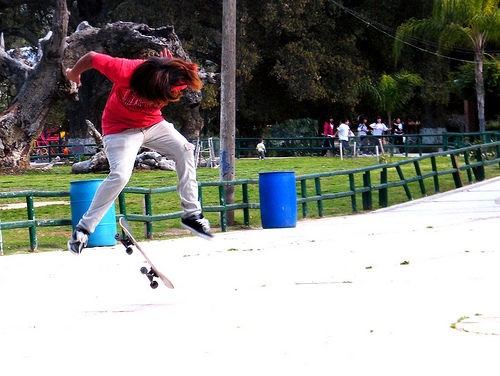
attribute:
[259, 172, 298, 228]
barrel — small, darker blue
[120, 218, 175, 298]
skateboard — black, wooden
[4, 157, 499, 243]
fence — green, wooden, small, metal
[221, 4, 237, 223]
pole — brown, wooden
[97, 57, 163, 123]
t-shirt — red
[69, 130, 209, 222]
pants — gray, khaki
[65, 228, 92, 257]
shoes — black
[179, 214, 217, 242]
shoes — black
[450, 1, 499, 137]
tree — young, tall, green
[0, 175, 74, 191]
grass — green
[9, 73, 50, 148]
tree trunk — brown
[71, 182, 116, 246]
trash can — jewel toned blue, lighter blue, blue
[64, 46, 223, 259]
skateboarder — young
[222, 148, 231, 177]
paint spot — blue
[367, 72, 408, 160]
weeping tree — young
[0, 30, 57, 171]
dead tree — large, gnarled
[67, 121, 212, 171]
branch — huge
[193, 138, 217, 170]
ladder — short, metal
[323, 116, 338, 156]
woman — young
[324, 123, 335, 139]
shirt — pink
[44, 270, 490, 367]
ground — cement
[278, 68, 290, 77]
leaves — green